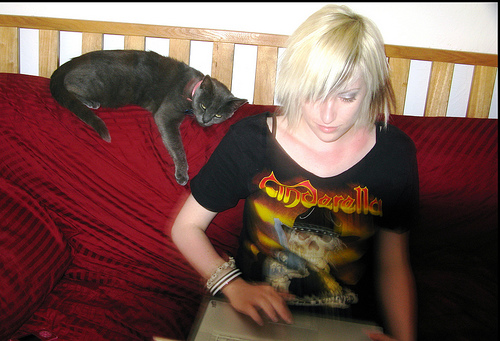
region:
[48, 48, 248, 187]
Black cat lazing on sofa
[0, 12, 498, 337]
Futon sofa with burgundy cushion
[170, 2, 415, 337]
Female sitting on futon sofa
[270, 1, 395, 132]
Dyed blonde hair with dark roots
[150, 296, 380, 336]
Gray laptop on female's lap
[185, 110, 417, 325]
Black Cinderella t-shirt with skeleton wearing cowboy hat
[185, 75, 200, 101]
Pink collar on black cat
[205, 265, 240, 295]
Black and white striped bracelet on girl's right wrist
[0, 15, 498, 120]
Wood frame for futon couch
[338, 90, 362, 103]
Eye shadow and mascara on girl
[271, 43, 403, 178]
the head of a woman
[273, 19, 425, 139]
the hair of a woman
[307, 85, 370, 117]
the eye of a woman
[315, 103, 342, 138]
the nose of a woman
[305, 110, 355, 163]
the mouth of a woman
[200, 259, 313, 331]
the hand of a woman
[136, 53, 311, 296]
the arm of a woman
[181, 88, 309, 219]
the shoulder of a woman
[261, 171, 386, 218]
the band name cinderalla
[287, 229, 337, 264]
a skull on the front of a shirt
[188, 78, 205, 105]
a pink collar on a cat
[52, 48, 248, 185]
a gray cat laying down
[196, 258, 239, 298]
bangles on a woman's wrist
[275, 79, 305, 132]
sharp edges on a woman's hair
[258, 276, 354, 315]
an electric guitar on a shirt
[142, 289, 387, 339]
a silver laptop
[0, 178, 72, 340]
a red striped satin pillow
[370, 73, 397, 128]
brown ombre highlights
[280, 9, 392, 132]
the girl has blonde hair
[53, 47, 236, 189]
the cat is laying down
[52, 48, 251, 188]
the cat is resting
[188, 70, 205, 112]
the cat is wearing a collar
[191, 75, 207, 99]
the collar is red in collar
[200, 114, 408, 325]
the shirt is black in color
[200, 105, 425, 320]
the girl is wearing a short sleeve shirt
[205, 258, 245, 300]
the woman is wearing bracelets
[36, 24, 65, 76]
wood plank on couch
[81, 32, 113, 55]
wood plank on couch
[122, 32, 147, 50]
wood plank on couch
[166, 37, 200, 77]
wood plank on couch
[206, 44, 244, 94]
wood plank on couch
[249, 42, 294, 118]
wood plank on couch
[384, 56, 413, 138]
wood plank on couch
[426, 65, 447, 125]
wood plank on couch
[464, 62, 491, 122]
wood plank on couch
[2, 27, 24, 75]
wood plank on couch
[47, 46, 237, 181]
the cat is gray and black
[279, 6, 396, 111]
the hair is blond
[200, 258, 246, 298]
bracelets on the wrist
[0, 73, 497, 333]
the cover is red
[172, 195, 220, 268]
the arm of a person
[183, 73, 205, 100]
the collar is pink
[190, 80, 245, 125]
the head of a cat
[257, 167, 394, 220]
word on a shirt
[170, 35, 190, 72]
slat in a bed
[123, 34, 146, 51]
slat in a bed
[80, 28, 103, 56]
slat in a bed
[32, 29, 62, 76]
slat in a bed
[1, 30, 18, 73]
slat in a bed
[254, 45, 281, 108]
slat in a bed